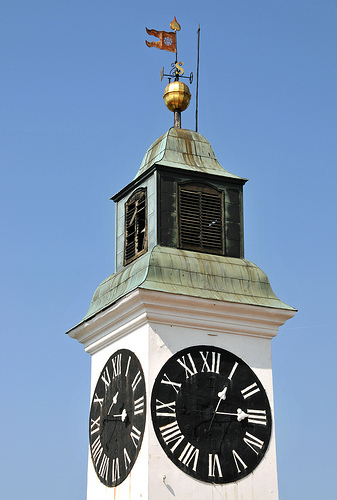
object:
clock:
[150, 344, 275, 490]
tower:
[63, 15, 298, 500]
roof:
[65, 245, 298, 358]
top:
[144, 16, 191, 56]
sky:
[25, 75, 112, 218]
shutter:
[175, 177, 225, 257]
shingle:
[167, 129, 195, 169]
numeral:
[199, 350, 221, 375]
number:
[177, 352, 199, 380]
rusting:
[98, 243, 161, 282]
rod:
[193, 22, 200, 131]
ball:
[162, 79, 191, 112]